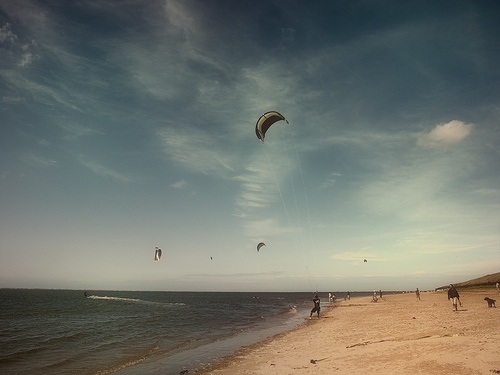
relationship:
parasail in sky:
[151, 234, 172, 274] [114, 225, 198, 275]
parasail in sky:
[254, 109, 292, 145] [2, 0, 499, 291]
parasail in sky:
[359, 257, 375, 268] [349, 247, 386, 273]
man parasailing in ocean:
[84, 291, 90, 298] [49, 267, 184, 327]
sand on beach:
[303, 331, 413, 359] [304, 308, 488, 371]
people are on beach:
[412, 288, 424, 307] [0, 294, 335, 371]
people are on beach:
[369, 290, 380, 305] [0, 294, 335, 371]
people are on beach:
[443, 283, 462, 313] [0, 294, 335, 371]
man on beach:
[309, 291, 320, 319] [221, 282, 493, 369]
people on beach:
[415, 288, 420, 302] [221, 282, 493, 369]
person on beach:
[342, 292, 347, 302] [221, 282, 493, 369]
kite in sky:
[254, 110, 289, 144] [2, 0, 499, 291]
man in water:
[80, 285, 95, 300] [2, 288, 327, 374]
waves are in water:
[84, 289, 190, 307] [19, 289, 275, 334]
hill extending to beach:
[430, 268, 498, 291] [61, 191, 491, 368]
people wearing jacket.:
[447, 284, 459, 313] [446, 279, 461, 298]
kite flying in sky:
[250, 108, 293, 140] [157, 65, 357, 216]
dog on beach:
[478, 290, 498, 307] [1, 283, 498, 373]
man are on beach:
[309, 291, 320, 319] [326, 287, 485, 355]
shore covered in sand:
[236, 280, 497, 372] [286, 322, 443, 357]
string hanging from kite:
[258, 123, 320, 295] [255, 109, 290, 147]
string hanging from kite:
[258, 123, 320, 295] [252, 243, 267, 255]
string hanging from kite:
[258, 123, 320, 295] [152, 245, 164, 262]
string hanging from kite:
[258, 123, 320, 295] [363, 260, 368, 264]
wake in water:
[80, 287, 135, 305] [30, 284, 244, 344]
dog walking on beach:
[484, 297, 497, 308] [224, 291, 485, 369]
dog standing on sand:
[484, 297, 497, 308] [200, 290, 499, 374]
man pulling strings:
[302, 287, 323, 320] [262, 117, 320, 299]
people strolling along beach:
[447, 284, 459, 313] [176, 285, 495, 372]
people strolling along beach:
[415, 288, 420, 302] [176, 285, 495, 372]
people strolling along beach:
[370, 290, 378, 303] [176, 285, 495, 372]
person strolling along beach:
[345, 290, 350, 300] [176, 285, 495, 372]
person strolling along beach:
[379, 288, 381, 295] [176, 285, 495, 372]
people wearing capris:
[447, 284, 459, 313] [442, 289, 468, 307]